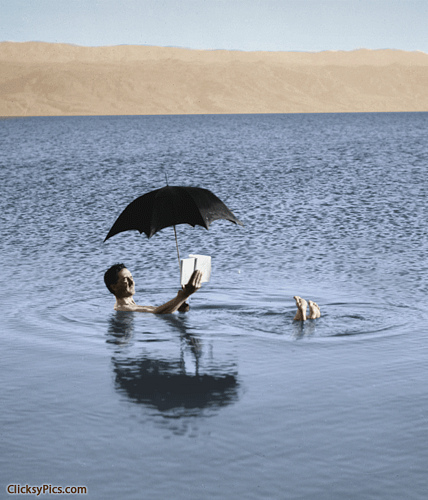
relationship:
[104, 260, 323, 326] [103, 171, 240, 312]
person holding umbrella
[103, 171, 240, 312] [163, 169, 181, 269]
umbrella has pole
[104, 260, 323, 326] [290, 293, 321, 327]
person has feet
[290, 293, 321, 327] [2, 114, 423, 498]
feet are out of water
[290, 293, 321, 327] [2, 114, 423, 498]
feet are above water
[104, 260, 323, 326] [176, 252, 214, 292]
person holding book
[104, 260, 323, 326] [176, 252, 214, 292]
person reads book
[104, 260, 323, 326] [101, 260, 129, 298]
person has hair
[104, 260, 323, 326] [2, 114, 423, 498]
person in water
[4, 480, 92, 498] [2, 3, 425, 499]
clicksypics.com on bottom of image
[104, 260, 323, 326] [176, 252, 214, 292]
person reading book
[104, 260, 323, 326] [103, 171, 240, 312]
person holds umbrella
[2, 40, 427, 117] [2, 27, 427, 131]
sand in background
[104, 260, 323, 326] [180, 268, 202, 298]
man has right hand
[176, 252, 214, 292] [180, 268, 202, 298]
book in right hand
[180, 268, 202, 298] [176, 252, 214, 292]
right hand holding book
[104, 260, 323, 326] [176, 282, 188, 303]
person has left hand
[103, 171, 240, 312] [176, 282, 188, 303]
umbrella in left hand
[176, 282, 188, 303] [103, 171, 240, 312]
left hand holds umbrella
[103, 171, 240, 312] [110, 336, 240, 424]
umbrella casts reflection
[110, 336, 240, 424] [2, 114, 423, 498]
reflection in water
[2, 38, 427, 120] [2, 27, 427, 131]
mountains are in background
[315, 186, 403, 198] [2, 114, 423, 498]
ripple in water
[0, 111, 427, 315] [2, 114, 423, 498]
ripple in water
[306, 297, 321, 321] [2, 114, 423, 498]
foot sticking out of water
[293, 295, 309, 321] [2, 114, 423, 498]
feet sticking out of water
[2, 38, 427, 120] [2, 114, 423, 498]
hill behind water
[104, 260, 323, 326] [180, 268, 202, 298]
person has right hand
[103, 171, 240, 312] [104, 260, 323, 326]
umbrella over person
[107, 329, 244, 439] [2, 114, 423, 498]
reflection in water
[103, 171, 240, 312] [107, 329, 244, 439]
umbrella casts reflection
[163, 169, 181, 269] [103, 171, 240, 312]
pole underneath umbrella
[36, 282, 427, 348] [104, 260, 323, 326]
ripple around person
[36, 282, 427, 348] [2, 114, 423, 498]
ripple in water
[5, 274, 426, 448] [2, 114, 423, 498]
light on water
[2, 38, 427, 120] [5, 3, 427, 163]
mountains are in distance